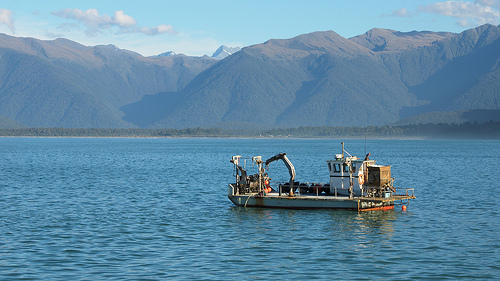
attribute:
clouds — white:
[50, 8, 175, 40]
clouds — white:
[2, 6, 22, 34]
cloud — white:
[0, 9, 17, 34]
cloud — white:
[48, 8, 179, 40]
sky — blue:
[191, 10, 261, 29]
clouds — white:
[66, 12, 217, 92]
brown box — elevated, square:
[363, 165, 393, 186]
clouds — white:
[0, 0, 499, 56]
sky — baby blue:
[46, 5, 216, 35]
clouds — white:
[432, 4, 485, 20]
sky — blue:
[97, 4, 465, 57]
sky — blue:
[132, 4, 371, 60]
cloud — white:
[60, 8, 135, 30]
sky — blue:
[162, 2, 331, 23]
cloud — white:
[432, 3, 497, 27]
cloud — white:
[385, 2, 416, 26]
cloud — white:
[45, 5, 173, 42]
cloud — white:
[1, 11, 32, 38]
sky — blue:
[2, 3, 497, 60]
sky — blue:
[165, 6, 227, 43]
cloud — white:
[51, 6, 112, 36]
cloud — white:
[110, 7, 132, 28]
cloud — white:
[381, 0, 497, 27]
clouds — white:
[1, 1, 499, 36]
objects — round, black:
[323, 185, 328, 193]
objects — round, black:
[308, 182, 317, 197]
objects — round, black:
[300, 182, 307, 191]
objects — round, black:
[281, 182, 296, 190]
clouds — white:
[413, 4, 453, 29]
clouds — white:
[41, 2, 183, 49]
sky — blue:
[74, 10, 174, 39]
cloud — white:
[69, 9, 197, 39]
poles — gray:
[232, 154, 264, 194]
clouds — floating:
[48, 11, 172, 41]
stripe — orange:
[355, 205, 396, 212]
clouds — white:
[63, 9, 165, 35]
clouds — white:
[62, 11, 169, 33]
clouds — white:
[56, 14, 171, 35]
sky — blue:
[4, 2, 498, 54]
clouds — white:
[49, 6, 216, 56]